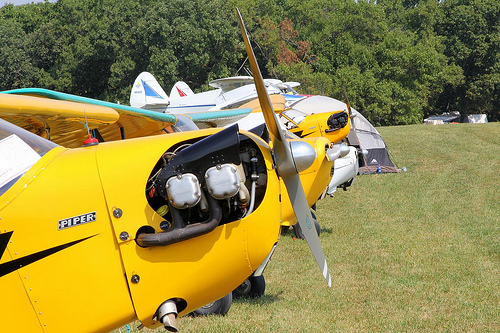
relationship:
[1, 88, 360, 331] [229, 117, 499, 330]
plane on field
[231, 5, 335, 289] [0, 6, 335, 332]
propeller front of airplane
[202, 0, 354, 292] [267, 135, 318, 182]
propeller attached to nose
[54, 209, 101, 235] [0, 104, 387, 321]
logo on plane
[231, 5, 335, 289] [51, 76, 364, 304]
propeller front of plane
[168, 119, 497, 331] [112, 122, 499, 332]
grass in field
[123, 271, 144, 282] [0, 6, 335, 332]
screw on side of airplane